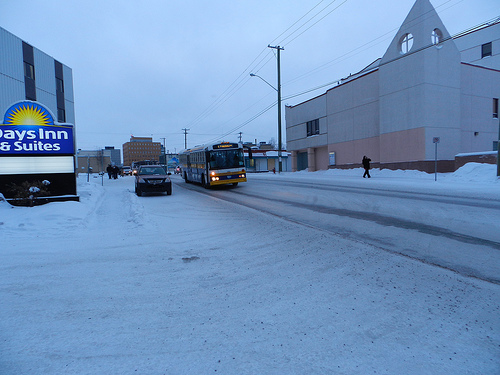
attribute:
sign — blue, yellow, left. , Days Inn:
[1, 99, 77, 177]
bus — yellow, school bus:
[173, 136, 250, 187]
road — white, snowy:
[104, 165, 499, 375]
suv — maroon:
[132, 164, 174, 197]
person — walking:
[358, 155, 376, 179]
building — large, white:
[279, 1, 499, 172]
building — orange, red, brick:
[122, 136, 167, 171]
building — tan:
[78, 140, 123, 173]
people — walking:
[105, 160, 123, 180]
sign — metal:
[430, 134, 444, 184]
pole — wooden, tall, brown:
[275, 48, 283, 152]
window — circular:
[396, 32, 417, 54]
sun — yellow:
[7, 107, 51, 128]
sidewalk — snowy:
[253, 161, 499, 195]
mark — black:
[181, 256, 200, 264]